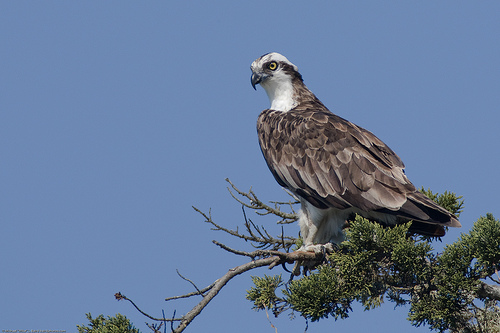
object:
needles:
[256, 216, 496, 332]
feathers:
[399, 196, 430, 222]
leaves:
[398, 169, 463, 211]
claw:
[321, 245, 326, 255]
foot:
[294, 242, 339, 254]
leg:
[288, 197, 339, 256]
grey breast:
[246, 114, 365, 204]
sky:
[2, 0, 243, 167]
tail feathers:
[409, 189, 463, 240]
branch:
[118, 179, 498, 331]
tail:
[355, 165, 461, 237]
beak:
[250, 74, 260, 92]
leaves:
[305, 276, 464, 306]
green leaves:
[280, 220, 437, 305]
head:
[243, 50, 305, 90]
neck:
[259, 76, 321, 105]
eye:
[268, 61, 279, 71]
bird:
[248, 50, 462, 255]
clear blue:
[11, 7, 491, 322]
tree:
[71, 162, 500, 333]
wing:
[257, 109, 431, 220]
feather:
[353, 155, 373, 172]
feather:
[348, 160, 373, 190]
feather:
[375, 170, 407, 190]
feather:
[368, 180, 398, 207]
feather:
[311, 160, 336, 195]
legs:
[302, 204, 340, 248]